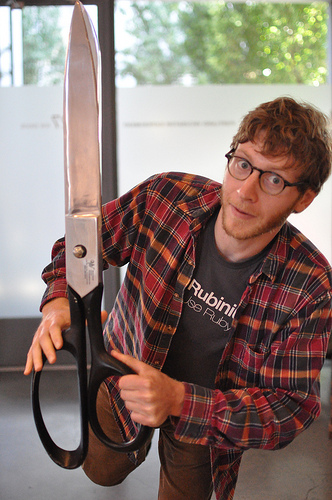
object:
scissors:
[33, 0, 157, 469]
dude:
[18, 91, 331, 499]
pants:
[82, 354, 148, 500]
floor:
[0, 356, 331, 496]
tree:
[273, 0, 331, 83]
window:
[1, 1, 113, 321]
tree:
[188, 1, 213, 87]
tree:
[21, 6, 66, 83]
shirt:
[40, 167, 331, 499]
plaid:
[284, 287, 300, 318]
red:
[309, 331, 328, 360]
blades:
[63, 0, 106, 296]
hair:
[224, 91, 330, 200]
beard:
[217, 197, 293, 242]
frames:
[222, 145, 310, 203]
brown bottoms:
[167, 480, 196, 497]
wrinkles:
[158, 423, 213, 500]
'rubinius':
[186, 278, 239, 318]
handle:
[29, 282, 89, 470]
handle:
[84, 282, 146, 450]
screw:
[72, 243, 87, 262]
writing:
[82, 254, 96, 291]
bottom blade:
[82, 1, 111, 206]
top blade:
[61, 1, 105, 212]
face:
[219, 139, 301, 241]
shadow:
[9, 377, 22, 407]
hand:
[22, 296, 105, 373]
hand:
[108, 347, 171, 426]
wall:
[4, 84, 331, 319]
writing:
[14, 107, 254, 135]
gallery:
[1, 0, 331, 499]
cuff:
[176, 372, 214, 445]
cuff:
[40, 273, 71, 314]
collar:
[177, 197, 289, 287]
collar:
[207, 210, 278, 268]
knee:
[80, 442, 136, 491]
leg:
[157, 421, 223, 498]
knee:
[153, 494, 215, 498]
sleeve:
[174, 225, 330, 448]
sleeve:
[36, 175, 148, 310]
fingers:
[52, 320, 66, 353]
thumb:
[66, 308, 105, 334]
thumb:
[107, 345, 141, 373]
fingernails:
[55, 338, 65, 351]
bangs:
[230, 110, 312, 171]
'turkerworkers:
[43, 96, 332, 498]